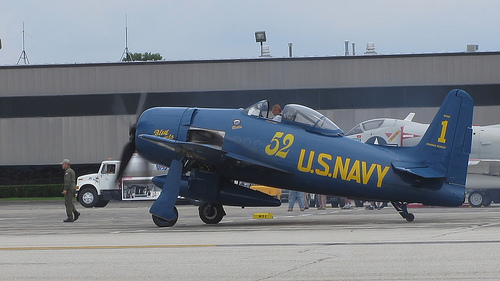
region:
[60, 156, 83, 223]
man standing in front of plane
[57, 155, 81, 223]
man walking away from plane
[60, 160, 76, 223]
man wearing green work suit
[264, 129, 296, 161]
yellow writing on blue plane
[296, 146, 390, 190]
yellow writing on blue plane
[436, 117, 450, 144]
yellow writing on blue plane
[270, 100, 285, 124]
man sitting in cockpit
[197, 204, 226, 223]
right front wheel of plane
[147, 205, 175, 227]
left front wheel of plane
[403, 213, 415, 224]
back wheel of plane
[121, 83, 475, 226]
a plane on the runway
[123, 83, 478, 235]
the plane is blue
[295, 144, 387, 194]
yellow letters on the plane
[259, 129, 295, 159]
the number 52 on the plane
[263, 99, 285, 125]
a pilot in the plane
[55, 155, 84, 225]
a man walking on the runway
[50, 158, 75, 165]
he is wearing a green cap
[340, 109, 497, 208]
a white plane behind the blue plane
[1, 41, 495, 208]
an airport behind the planes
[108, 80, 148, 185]
propellers on the front of the plane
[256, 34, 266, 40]
a flag light on top of a building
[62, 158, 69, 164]
the cap of a man walking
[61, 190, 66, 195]
the hand of a man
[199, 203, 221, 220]
the wheel of a navy plane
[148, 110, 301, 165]
a blue navy plane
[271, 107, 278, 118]
a pilot in the cock pit of the plane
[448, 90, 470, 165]
the tail of a navy plane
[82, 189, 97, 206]
the front wheel of a white truck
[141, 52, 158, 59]
leaves of a tree in the background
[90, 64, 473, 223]
a blue airplane with yellow signage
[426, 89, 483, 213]
the tail of an airplane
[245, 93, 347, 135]
a open glass canopy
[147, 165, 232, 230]
the landing gear of a plane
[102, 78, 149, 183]
the propeller on a plane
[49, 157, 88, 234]
a person in a green uniform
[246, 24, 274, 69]
a flood light on the roof of a building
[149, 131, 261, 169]
the wing of an airplane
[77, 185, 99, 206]
the wheel of a vehicle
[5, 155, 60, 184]
windows on a building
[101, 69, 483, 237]
U.S. NAVY AIR PLANE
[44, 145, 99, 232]
US NAVY MARINE IN GREEN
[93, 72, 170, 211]
PERPELLER ON BLUE PLANE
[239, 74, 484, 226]
PILOT OF AN AIRPLANE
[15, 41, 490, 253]
US NAVY AIRPORT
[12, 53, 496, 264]
PLANE RIDING ON AIRSTRIP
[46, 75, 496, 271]
PLAIN GETTING READY TO TAKE OFF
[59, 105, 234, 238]
WHITE TRUCK THAT BRINGS FUEL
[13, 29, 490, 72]
ANTENNAS AND LIGHTS ON TOP OF AIRPORT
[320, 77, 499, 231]
WHITE AIRCRAFT IN AIRPORT